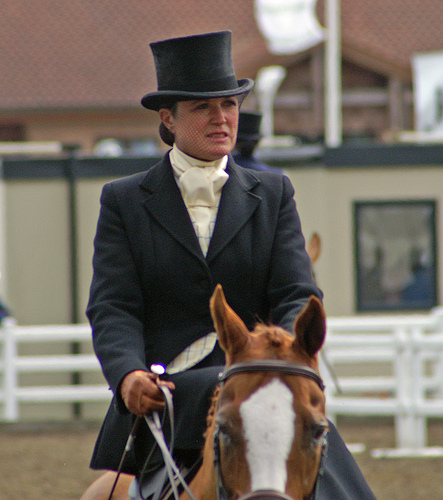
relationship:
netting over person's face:
[155, 99, 240, 159] [175, 95, 241, 154]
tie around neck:
[166, 142, 234, 248] [169, 147, 235, 176]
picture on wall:
[347, 196, 438, 311] [287, 145, 440, 309]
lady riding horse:
[68, 26, 366, 481] [188, 281, 332, 497]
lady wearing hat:
[68, 26, 366, 481] [138, 30, 253, 110]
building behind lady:
[0, 140, 437, 314] [78, 26, 345, 462]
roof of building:
[1, 0, 441, 139] [2, 0, 440, 144]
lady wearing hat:
[87, 26, 377, 500] [138, 30, 253, 110]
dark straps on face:
[210, 357, 330, 497] [212, 326, 327, 500]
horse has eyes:
[176, 273, 345, 496] [217, 405, 340, 446]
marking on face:
[239, 374, 300, 496] [212, 317, 328, 497]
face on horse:
[212, 317, 328, 497] [80, 282, 328, 497]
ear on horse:
[291, 287, 327, 353] [80, 282, 328, 497]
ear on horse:
[208, 282, 252, 360] [80, 282, 328, 497]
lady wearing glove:
[87, 26, 377, 500] [121, 367, 176, 419]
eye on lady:
[218, 95, 238, 108] [87, 26, 377, 500]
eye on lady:
[190, 102, 211, 111] [87, 26, 377, 500]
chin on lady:
[193, 137, 234, 156] [87, 26, 377, 500]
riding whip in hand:
[103, 360, 168, 497] [114, 366, 175, 419]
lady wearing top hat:
[87, 26, 377, 500] [136, 27, 258, 105]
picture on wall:
[352, 198, 437, 311] [297, 172, 357, 304]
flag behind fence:
[252, 0, 336, 58] [0, 302, 443, 461]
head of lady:
[142, 31, 255, 157] [87, 26, 377, 500]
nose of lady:
[209, 105, 228, 125] [87, 26, 377, 500]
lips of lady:
[202, 129, 231, 139] [87, 26, 377, 500]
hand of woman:
[122, 362, 174, 411] [83, 31, 378, 484]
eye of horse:
[216, 420, 229, 436] [169, 293, 328, 498]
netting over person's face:
[155, 99, 240, 164] [175, 95, 241, 154]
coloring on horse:
[233, 371, 299, 496] [80, 282, 328, 497]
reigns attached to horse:
[137, 380, 197, 496] [80, 282, 328, 497]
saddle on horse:
[118, 456, 191, 497] [80, 282, 328, 497]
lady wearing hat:
[87, 26, 377, 500] [135, 25, 256, 110]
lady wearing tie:
[87, 26, 377, 500] [166, 142, 230, 206]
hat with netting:
[115, 14, 265, 111] [155, 99, 240, 159]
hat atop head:
[115, 14, 265, 111] [159, 95, 239, 158]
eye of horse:
[307, 419, 328, 442] [80, 282, 328, 497]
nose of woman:
[209, 105, 228, 125] [83, 31, 378, 484]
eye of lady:
[190, 99, 212, 118] [87, 26, 377, 500]